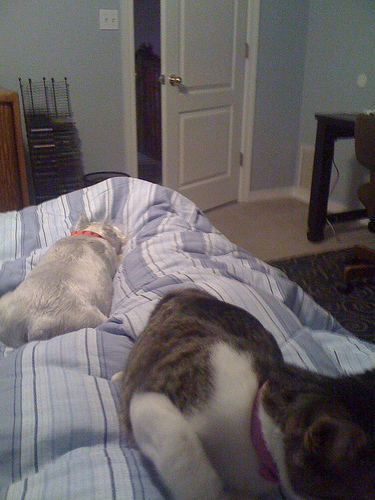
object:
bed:
[0, 176, 375, 494]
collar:
[244, 378, 283, 478]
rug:
[262, 242, 375, 342]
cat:
[0, 213, 128, 349]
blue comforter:
[0, 177, 375, 477]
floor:
[234, 196, 298, 238]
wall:
[13, 18, 86, 71]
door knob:
[156, 133, 178, 145]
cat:
[120, 284, 375, 500]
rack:
[17, 75, 85, 206]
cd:
[26, 124, 81, 151]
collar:
[70, 223, 106, 239]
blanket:
[0, 176, 375, 499]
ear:
[74, 290, 91, 310]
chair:
[355, 111, 375, 234]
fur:
[49, 270, 75, 294]